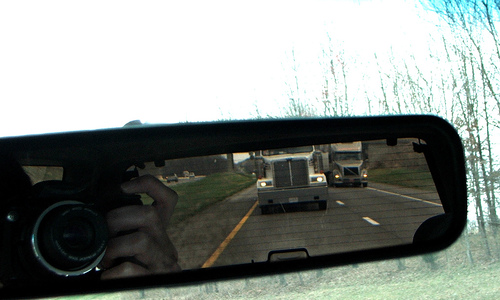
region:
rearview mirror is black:
[2, 114, 469, 298]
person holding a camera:
[1, 164, 181, 282]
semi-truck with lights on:
[254, 143, 329, 213]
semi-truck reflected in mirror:
[323, 140, 368, 189]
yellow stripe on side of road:
[201, 197, 260, 269]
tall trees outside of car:
[465, 53, 498, 243]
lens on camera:
[28, 198, 107, 276]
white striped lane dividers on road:
[333, 196, 380, 230]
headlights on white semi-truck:
[257, 176, 323, 188]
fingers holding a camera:
[99, 174, 183, 279]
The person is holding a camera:
[39, 167, 238, 267]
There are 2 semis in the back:
[237, 130, 452, 275]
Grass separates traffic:
[171, 165, 253, 234]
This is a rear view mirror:
[33, 112, 490, 255]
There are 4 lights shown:
[250, 156, 415, 214]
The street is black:
[221, 204, 393, 241]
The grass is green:
[181, 176, 278, 243]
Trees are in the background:
[253, 68, 498, 215]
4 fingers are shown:
[105, 168, 192, 293]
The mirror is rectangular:
[20, 101, 493, 289]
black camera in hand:
[12, 168, 146, 284]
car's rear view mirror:
[3, 112, 469, 292]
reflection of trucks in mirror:
[248, 145, 374, 210]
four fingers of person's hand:
[93, 170, 182, 278]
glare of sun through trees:
[182, 18, 408, 93]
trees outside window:
[373, 13, 486, 231]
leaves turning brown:
[456, 96, 488, 197]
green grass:
[363, 268, 479, 297]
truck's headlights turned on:
[335, 167, 366, 187]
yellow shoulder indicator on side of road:
[188, 190, 268, 270]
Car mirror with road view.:
[4, 133, 486, 296]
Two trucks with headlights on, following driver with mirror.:
[248, 140, 376, 205]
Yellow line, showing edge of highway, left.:
[207, 180, 252, 275]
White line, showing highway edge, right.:
[375, 180, 450, 216]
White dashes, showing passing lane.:
[337, 195, 393, 245]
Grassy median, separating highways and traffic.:
[183, 166, 237, 209]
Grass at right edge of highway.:
[388, 157, 443, 197]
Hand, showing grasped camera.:
[23, 183, 180, 280]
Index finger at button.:
[118, 174, 180, 210]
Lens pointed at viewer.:
[43, 205, 118, 279]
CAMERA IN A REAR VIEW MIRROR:
[11, 155, 185, 287]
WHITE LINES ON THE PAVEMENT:
[330, 192, 397, 236]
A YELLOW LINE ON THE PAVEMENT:
[195, 197, 267, 269]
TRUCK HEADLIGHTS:
[258, 169, 331, 193]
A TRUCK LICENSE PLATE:
[285, 191, 302, 208]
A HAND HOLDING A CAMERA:
[6, 174, 208, 284]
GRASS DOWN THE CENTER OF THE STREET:
[175, 158, 252, 218]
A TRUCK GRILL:
[271, 154, 321, 196]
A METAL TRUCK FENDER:
[253, 185, 342, 210]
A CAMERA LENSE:
[49, 203, 116, 265]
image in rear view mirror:
[0, 114, 467, 298]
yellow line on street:
[199, 201, 256, 267]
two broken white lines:
[334, 198, 380, 227]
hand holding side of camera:
[12, 173, 180, 281]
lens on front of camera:
[9, 176, 140, 277]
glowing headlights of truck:
[260, 175, 325, 189]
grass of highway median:
[175, 168, 253, 223]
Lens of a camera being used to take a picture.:
[29, 201, 109, 281]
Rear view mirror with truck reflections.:
[3, 113, 466, 298]